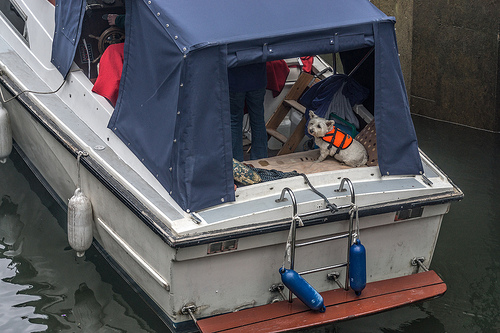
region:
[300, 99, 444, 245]
a dog inside a boat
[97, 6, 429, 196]
a blue canvas boat cabin cover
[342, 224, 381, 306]
a blue buoy on a rope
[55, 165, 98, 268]
a white buoy on a rope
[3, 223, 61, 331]
reflections on the water's surface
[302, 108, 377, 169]
a dog wearing an orange life vest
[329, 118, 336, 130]
the left ear of a dog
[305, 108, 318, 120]
the right ear of a dog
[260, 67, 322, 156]
wooden stairs inside a boat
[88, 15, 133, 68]
the navigation wheel of a boat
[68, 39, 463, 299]
this is a boat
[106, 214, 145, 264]
the boat is white in color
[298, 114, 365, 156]
this is a dog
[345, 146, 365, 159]
the dog is white in color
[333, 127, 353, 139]
this is a life jacket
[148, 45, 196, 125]
this is a tent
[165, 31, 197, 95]
the tent is blue in color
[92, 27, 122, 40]
this is a starring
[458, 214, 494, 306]
this is a water body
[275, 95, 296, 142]
this is a ladder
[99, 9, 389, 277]
this is the ship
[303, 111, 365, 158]
this is a dog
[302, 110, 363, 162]
the dog is small in size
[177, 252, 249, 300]
the ship is white in color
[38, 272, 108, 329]
this is the water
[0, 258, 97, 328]
the water is calm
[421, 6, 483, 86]
this is the wall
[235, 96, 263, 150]
these are the legs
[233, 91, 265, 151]
the legs are long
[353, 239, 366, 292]
the floater is blue in color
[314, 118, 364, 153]
A small white cat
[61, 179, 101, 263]
A small white container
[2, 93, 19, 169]
A small white container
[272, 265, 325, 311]
A small blue container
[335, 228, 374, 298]
A small blue container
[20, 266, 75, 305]
A dirty grey water in the road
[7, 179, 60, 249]
A dirty grey water in the road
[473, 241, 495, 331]
A dirty grey water in the road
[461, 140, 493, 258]
A dirty grey water in the road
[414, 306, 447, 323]
A dirty grey water in the road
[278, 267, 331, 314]
A blue oxygen tank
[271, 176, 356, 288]
A metal ladder on a boat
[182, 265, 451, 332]
A wooden plank for standing on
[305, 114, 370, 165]
A small white dog on a boat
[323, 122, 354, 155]
An orange life vest for a dog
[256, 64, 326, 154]
A small wooden step ladder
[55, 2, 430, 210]
A blue canvas tarp for a boat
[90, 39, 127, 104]
A red cloth covering something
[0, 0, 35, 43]
A boat window made of glass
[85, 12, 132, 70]
A boat steering wheel